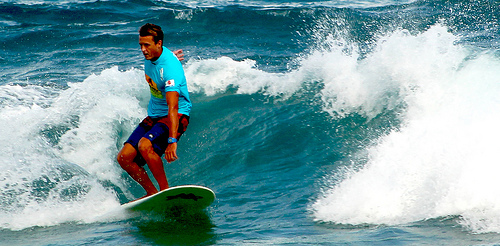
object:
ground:
[348, 106, 425, 121]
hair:
[138, 23, 163, 45]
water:
[272, 137, 499, 238]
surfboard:
[121, 184, 216, 209]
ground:
[356, 134, 438, 171]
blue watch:
[168, 137, 178, 143]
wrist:
[167, 136, 176, 144]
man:
[116, 23, 193, 203]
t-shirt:
[143, 45, 192, 118]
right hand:
[172, 49, 184, 61]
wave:
[0, 21, 500, 235]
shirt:
[144, 46, 193, 118]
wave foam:
[286, 11, 499, 236]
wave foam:
[0, 65, 149, 232]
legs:
[115, 136, 168, 203]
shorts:
[123, 113, 190, 166]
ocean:
[0, 0, 495, 244]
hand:
[163, 143, 177, 164]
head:
[138, 23, 164, 60]